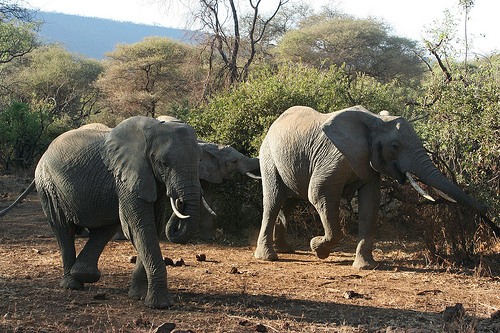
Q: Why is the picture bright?
A: The sun is out.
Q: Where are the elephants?
A: In the jungle.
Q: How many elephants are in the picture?
A: Three.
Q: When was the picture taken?
A: During the day.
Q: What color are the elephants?
A: Grey.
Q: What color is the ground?
A: Brown.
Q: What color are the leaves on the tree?
A: Green.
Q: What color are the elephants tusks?
A: White.